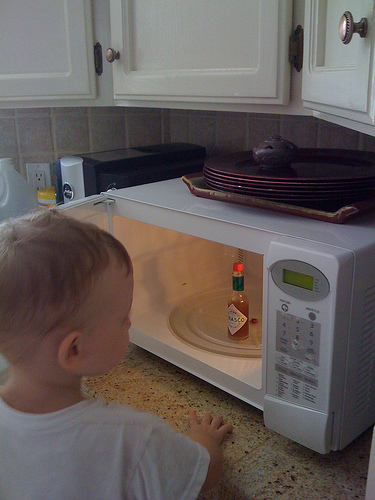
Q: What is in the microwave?
A: A bottle.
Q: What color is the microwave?
A: White.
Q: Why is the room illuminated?
A: Sunlight.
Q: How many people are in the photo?
A: One.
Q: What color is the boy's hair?
A: Blonde.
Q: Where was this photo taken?
A: In a kitchen.